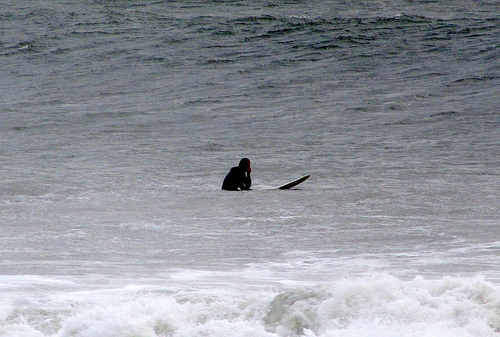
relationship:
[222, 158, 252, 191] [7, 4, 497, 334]
man surfing in beach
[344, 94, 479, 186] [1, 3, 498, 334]
ripples are in water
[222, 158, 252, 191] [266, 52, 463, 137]
man in water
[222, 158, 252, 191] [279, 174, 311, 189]
man on board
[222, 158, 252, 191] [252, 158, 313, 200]
man on surfboard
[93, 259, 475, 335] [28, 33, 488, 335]
wave from ocean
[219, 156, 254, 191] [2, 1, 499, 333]
man in ocean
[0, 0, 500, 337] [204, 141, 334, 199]
wave near surfer